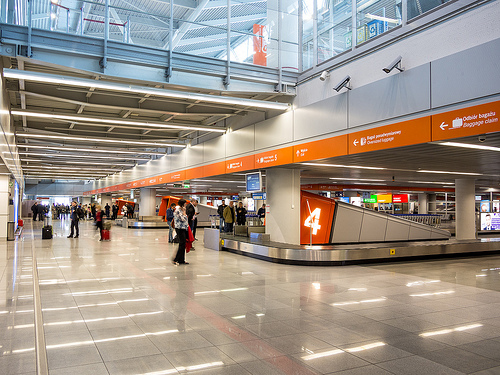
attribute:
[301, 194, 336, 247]
sign — orange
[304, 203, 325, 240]
4 — large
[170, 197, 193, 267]
woman — standing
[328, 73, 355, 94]
video camera — for safety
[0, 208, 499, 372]
floor — tiled, shiny, tan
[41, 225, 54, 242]
bag — sitting, red, black, dark colored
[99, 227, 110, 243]
bag — sitting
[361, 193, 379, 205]
sign — bright, green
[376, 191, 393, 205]
sign — in distance, yellow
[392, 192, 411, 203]
sign — bright, red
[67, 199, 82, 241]
person — standing, in background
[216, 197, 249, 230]
men — group, standing together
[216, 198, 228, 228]
man — in background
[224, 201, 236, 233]
man — in background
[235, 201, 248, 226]
man — standing, in background, waiting for luggage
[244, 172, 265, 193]
television screen — large, information screen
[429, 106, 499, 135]
sign — directional sign, orange, giving directions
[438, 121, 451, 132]
arrow — pointing left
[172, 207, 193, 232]
top — light, white, blue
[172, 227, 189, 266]
pants — dark, black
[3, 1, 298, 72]
window — large, paneled, glass, wall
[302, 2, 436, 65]
window — large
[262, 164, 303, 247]
pilliar — white, round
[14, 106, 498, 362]
baggage claim area — large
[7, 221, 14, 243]
trash can — silver, for the mall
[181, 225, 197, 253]
coat — red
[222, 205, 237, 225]
jacket — olive green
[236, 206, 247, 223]
coat — black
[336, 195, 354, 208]
sign — blue